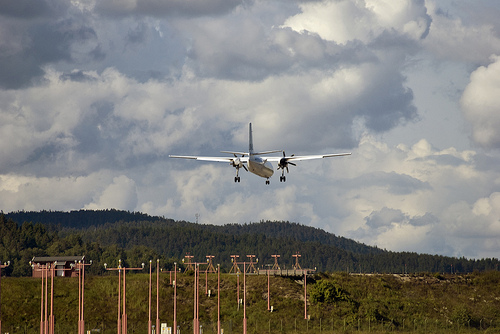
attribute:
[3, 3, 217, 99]
dark clouds — in the background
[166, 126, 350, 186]
white airplane — with propellers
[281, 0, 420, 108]
sun — hiding in clouds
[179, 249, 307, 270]
red structures — a line, in the distance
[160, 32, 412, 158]
clouds — dark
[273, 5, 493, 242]
clouds — fluffy, white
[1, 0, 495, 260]
sky — very cloudy, cloudy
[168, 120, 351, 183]
airplane — with landing gear down, white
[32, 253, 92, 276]
house — tiny, red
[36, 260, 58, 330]
posts — tall, pink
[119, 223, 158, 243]
trees — green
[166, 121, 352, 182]
plane — silver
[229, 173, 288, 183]
wheels — three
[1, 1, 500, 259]
clouds — fluffy